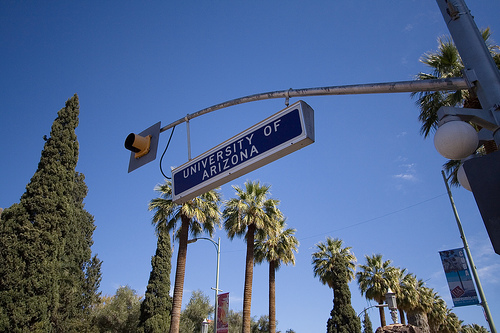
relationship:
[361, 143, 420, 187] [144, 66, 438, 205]
cloud in sky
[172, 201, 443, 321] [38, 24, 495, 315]
trees in photo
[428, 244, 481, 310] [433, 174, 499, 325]
banner on pole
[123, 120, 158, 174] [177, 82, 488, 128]
light on pole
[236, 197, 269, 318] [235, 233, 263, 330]
tree has trunk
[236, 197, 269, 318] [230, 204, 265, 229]
tree has leaves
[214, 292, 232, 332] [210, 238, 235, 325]
banner on pole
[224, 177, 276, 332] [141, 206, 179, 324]
tree near pine tree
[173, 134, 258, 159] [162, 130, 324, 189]
university on sign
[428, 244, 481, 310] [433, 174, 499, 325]
flag on pole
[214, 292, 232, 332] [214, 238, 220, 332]
banner on pole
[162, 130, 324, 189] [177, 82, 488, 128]
sign on pole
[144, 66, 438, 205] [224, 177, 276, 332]
sky behind tree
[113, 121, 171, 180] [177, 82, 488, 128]
light on pole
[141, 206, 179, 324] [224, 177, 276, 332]
pine tree by tree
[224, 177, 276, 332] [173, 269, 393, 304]
tree in row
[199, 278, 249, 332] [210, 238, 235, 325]
banner on pole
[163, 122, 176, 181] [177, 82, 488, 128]
wire on pole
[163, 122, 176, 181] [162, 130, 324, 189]
wire near sign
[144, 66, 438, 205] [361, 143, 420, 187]
sky has cloud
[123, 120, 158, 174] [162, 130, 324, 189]
light by sign